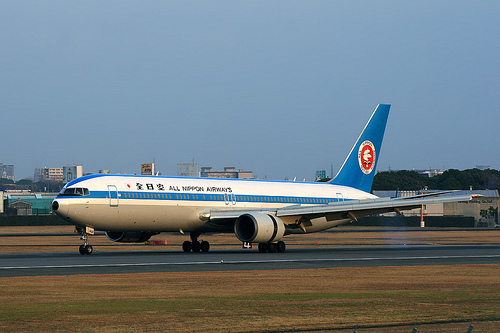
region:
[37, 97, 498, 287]
the plane is white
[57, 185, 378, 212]
the plane has a blue stripe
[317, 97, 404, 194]
the plane has a blue tail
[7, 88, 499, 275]
the plane is on the runway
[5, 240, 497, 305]
the runway is black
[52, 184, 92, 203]
the plane has windows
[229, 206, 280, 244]
the plane has an engine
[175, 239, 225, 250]
the plane's wheels are black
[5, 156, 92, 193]
there are buildings in the background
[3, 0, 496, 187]
the sky is blue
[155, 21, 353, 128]
the sky is blue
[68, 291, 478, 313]
there is grass on ground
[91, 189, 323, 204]
the border of plane is blue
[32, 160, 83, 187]
buildings in the back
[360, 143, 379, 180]
there is a emblem on the tail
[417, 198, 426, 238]
a red pole in the back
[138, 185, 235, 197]
the name of the aircraft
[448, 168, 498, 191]
trees in the back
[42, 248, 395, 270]
markings on the runway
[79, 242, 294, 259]
eight wheels for landing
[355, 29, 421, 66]
part of the sky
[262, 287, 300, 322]
part of the ground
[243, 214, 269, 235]
part of an engine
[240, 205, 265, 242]
edge of an engine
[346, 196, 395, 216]
part of a wing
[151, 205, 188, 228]
edge of a plane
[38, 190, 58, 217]
part of a tip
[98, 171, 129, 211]
part of a door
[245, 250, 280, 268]
part of a runway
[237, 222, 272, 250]
part of an engine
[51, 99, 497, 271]
airplane on the runway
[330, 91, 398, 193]
blue tail with a red and white circle painted on it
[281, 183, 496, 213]
thin and long airplane wing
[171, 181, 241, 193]
black lettering that says "All Nippon Airways"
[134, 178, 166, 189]
three black Japanese characters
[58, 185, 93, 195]
cockpit window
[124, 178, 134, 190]
red dot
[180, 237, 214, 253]
three black airplane wheels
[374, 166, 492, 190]
dark green treetops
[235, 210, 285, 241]
silver and black jet engine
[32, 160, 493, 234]
one plane on the tarmac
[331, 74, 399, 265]
plane has blue tail with red and white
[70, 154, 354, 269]
white plane with blue stripe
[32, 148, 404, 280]
white plane with black lettering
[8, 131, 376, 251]
city visible in the background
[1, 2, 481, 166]
no clouds in the sky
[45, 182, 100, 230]
black nose on plane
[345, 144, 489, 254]
trees can be seen in photograph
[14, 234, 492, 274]
white lines on the pavement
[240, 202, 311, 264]
one engine in photograph